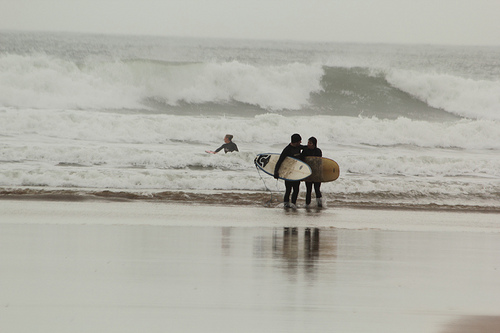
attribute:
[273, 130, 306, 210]
surfer — walking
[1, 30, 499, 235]
ocean — large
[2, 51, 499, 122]
wave — big, high, beginning to crash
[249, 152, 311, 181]
surfboard — carried, white, black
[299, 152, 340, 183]
surfboard — carried, yellow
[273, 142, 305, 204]
wetsuit — black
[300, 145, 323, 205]
wetsuit — black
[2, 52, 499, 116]
foam — white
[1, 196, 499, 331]
shore — sandy, flat, wet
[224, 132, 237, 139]
hair — pulled back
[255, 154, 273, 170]
design — black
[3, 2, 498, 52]
sky — gray, cloudy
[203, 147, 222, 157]
surfboard — red